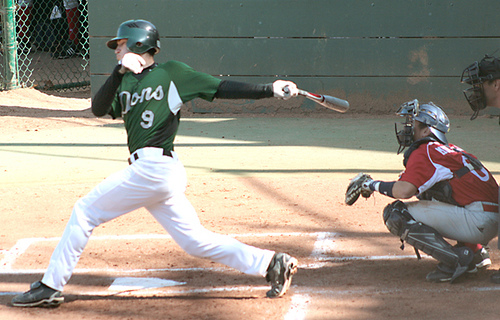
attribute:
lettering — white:
[113, 84, 170, 116]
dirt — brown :
[0, 100, 498, 303]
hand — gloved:
[344, 170, 381, 202]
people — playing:
[7, 9, 494, 319]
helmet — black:
[400, 90, 451, 145]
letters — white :
[113, 85, 175, 120]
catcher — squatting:
[339, 100, 496, 288]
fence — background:
[7, 8, 110, 96]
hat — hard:
[394, 90, 465, 139]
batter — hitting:
[9, 15, 299, 319]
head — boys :
[103, 14, 170, 57]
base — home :
[104, 264, 189, 301]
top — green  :
[94, 50, 228, 153]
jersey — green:
[106, 58, 223, 147]